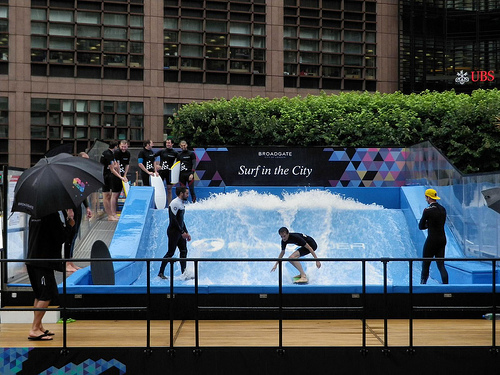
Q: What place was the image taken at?
A: It was taken at the city.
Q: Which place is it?
A: It is a city.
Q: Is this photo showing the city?
A: Yes, it is showing the city.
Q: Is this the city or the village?
A: It is the city.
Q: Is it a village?
A: No, it is a city.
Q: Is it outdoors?
A: Yes, it is outdoors.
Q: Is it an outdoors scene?
A: Yes, it is outdoors.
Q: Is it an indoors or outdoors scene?
A: It is outdoors.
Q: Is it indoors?
A: No, it is outdoors.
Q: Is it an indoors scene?
A: No, it is outdoors.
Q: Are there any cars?
A: No, there are no cars.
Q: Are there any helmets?
A: No, there are no helmets.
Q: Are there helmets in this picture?
A: No, there are no helmets.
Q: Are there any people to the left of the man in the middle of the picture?
A: Yes, there is a person to the left of the man.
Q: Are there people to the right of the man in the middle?
A: No, the person is to the left of the man.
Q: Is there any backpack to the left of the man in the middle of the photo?
A: No, there is a person to the left of the man.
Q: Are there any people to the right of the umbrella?
A: Yes, there is a person to the right of the umbrella.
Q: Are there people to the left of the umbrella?
A: No, the person is to the right of the umbrella.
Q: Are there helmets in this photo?
A: No, there are no helmets.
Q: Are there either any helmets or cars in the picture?
A: No, there are no helmets or cars.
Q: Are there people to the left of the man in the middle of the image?
A: Yes, there is a person to the left of the man.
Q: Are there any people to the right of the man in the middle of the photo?
A: No, the person is to the left of the man.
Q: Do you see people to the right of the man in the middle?
A: No, the person is to the left of the man.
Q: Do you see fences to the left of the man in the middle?
A: No, there is a person to the left of the man.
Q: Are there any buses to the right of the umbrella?
A: No, there is a person to the right of the umbrella.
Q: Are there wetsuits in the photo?
A: Yes, there is a wetsuit.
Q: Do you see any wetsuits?
A: Yes, there is a wetsuit.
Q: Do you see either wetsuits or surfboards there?
A: Yes, there is a wetsuit.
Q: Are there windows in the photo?
A: Yes, there are windows.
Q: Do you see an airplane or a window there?
A: Yes, there are windows.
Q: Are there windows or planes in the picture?
A: Yes, there are windows.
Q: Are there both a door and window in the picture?
A: No, there are windows but no doors.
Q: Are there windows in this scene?
A: Yes, there are windows.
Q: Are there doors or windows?
A: Yes, there are windows.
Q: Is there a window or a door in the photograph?
A: Yes, there are windows.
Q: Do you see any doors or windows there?
A: Yes, there are windows.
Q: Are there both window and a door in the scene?
A: No, there are windows but no doors.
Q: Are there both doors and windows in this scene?
A: No, there are windows but no doors.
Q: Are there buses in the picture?
A: No, there are no buses.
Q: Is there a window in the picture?
A: Yes, there are windows.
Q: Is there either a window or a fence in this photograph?
A: Yes, there are windows.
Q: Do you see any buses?
A: No, there are no buses.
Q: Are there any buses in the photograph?
A: No, there are no buses.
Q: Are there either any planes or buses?
A: No, there are no buses or planes.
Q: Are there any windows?
A: Yes, there are windows.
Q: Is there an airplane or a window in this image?
A: Yes, there are windows.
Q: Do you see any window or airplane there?
A: Yes, there are windows.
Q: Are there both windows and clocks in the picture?
A: No, there are windows but no clocks.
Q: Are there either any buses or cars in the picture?
A: No, there are no cars or buses.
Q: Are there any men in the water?
A: Yes, there is a man in the water.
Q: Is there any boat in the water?
A: No, there is a man in the water.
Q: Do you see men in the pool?
A: Yes, there is a man in the pool.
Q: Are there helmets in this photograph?
A: No, there are no helmets.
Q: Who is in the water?
A: The man is in the water.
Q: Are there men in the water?
A: Yes, there is a man in the water.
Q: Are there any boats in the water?
A: No, there is a man in the water.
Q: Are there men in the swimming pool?
A: Yes, there is a man in the swimming pool.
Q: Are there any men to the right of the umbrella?
A: Yes, there is a man to the right of the umbrella.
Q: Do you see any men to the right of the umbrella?
A: Yes, there is a man to the right of the umbrella.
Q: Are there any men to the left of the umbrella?
A: No, the man is to the right of the umbrella.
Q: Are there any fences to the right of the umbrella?
A: No, there is a man to the right of the umbrella.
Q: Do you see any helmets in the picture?
A: No, there are no helmets.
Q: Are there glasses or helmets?
A: No, there are no helmets or glasses.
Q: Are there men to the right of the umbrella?
A: Yes, there is a man to the right of the umbrella.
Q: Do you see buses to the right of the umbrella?
A: No, there is a man to the right of the umbrella.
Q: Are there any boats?
A: No, there are no boats.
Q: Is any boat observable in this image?
A: No, there are no boats.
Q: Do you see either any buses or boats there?
A: No, there are no boats or buses.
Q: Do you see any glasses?
A: No, there are no glasses.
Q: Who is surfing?
A: The man is surfing.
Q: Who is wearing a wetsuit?
A: The man is wearing a wetsuit.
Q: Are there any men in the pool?
A: Yes, there is a man in the pool.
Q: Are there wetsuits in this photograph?
A: Yes, there is a wetsuit.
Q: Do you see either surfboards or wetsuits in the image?
A: Yes, there is a wetsuit.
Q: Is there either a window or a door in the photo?
A: Yes, there are windows.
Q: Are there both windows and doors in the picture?
A: No, there are windows but no doors.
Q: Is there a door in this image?
A: No, there are no doors.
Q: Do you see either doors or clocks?
A: No, there are no doors or clocks.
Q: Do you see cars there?
A: No, there are no cars.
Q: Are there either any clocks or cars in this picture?
A: No, there are no cars or clocks.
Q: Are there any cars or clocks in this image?
A: No, there are no cars or clocks.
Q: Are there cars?
A: No, there are no cars.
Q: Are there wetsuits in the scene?
A: Yes, there is a wetsuit.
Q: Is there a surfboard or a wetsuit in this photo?
A: Yes, there is a wetsuit.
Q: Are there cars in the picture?
A: No, there are no cars.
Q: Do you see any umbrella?
A: Yes, there is an umbrella.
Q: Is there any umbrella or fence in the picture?
A: Yes, there is an umbrella.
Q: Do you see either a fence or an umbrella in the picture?
A: Yes, there is an umbrella.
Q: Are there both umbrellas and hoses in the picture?
A: No, there is an umbrella but no hoses.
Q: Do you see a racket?
A: No, there are no rackets.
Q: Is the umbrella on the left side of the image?
A: Yes, the umbrella is on the left of the image.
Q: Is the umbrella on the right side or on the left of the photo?
A: The umbrella is on the left of the image.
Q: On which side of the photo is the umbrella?
A: The umbrella is on the left of the image.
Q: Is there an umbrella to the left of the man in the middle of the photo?
A: Yes, there is an umbrella to the left of the man.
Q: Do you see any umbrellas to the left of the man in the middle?
A: Yes, there is an umbrella to the left of the man.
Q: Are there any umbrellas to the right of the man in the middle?
A: No, the umbrella is to the left of the man.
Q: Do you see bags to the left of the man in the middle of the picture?
A: No, there is an umbrella to the left of the man.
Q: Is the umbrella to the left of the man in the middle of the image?
A: Yes, the umbrella is to the left of the man.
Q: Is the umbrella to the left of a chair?
A: No, the umbrella is to the left of the man.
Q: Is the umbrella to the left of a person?
A: Yes, the umbrella is to the left of a person.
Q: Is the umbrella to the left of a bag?
A: No, the umbrella is to the left of a person.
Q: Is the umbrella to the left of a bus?
A: No, the umbrella is to the left of a person.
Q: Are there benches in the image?
A: No, there are no benches.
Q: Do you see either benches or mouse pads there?
A: No, there are no benches or mouse pads.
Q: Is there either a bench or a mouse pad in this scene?
A: No, there are no benches or mouse pads.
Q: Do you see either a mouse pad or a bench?
A: No, there are no benches or mouse pads.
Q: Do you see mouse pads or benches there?
A: No, there are no benches or mouse pads.